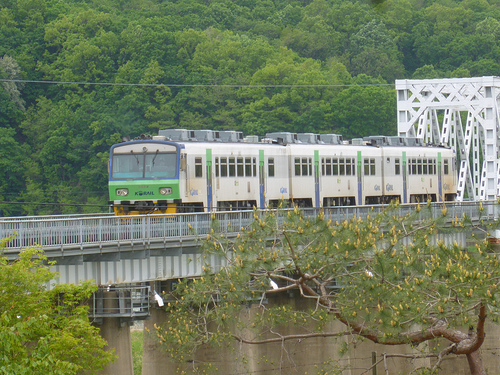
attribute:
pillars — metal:
[393, 78, 499, 203]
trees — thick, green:
[4, 1, 499, 69]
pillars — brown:
[102, 290, 121, 317]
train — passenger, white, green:
[103, 125, 455, 221]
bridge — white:
[383, 65, 498, 134]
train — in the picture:
[103, 121, 461, 227]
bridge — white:
[424, 197, 496, 242]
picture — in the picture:
[8, 0, 497, 371]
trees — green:
[10, 24, 389, 139]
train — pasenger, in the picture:
[106, 134, 456, 220]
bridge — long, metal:
[0, 204, 496, 261]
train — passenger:
[118, 102, 481, 200]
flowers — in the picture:
[352, 234, 392, 290]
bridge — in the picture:
[44, 147, 469, 327]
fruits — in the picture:
[335, 222, 413, 290]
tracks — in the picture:
[66, 187, 478, 274]